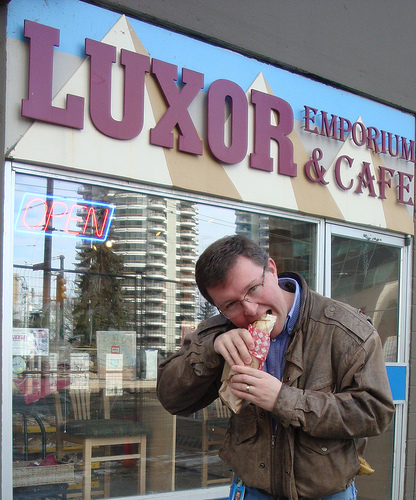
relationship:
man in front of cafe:
[155, 232, 396, 498] [0, 0, 415, 498]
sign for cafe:
[26, 22, 413, 227] [14, 168, 386, 499]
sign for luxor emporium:
[26, 22, 413, 227] [19, 18, 414, 167]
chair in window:
[194, 424, 216, 457] [16, 172, 316, 497]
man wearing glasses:
[155, 232, 396, 498] [217, 257, 268, 319]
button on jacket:
[326, 303, 337, 313] [204, 314, 362, 483]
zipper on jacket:
[267, 414, 280, 498] [154, 268, 396, 499]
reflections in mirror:
[33, 252, 127, 351] [11, 163, 251, 490]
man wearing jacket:
[155, 232, 396, 498] [178, 295, 368, 482]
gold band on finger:
[245, 384, 248, 391] [240, 381, 255, 396]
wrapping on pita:
[244, 325, 271, 368] [217, 312, 278, 417]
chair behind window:
[47, 413, 155, 498] [38, 293, 144, 444]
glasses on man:
[215, 260, 267, 319] [155, 232, 396, 498]